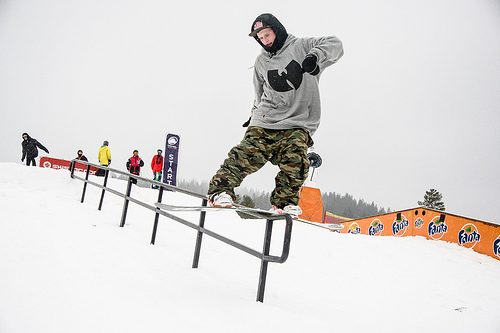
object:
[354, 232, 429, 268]
snow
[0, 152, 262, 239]
hill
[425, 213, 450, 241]
logo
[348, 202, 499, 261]
fence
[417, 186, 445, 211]
tree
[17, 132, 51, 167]
people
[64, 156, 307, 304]
rail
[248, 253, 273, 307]
pole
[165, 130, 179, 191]
sign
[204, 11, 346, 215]
boy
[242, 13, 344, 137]
hoodie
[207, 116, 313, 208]
camoflauge pants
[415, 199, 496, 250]
divider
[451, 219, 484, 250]
fanta soda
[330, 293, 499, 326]
ground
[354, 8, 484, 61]
sky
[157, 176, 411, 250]
mountain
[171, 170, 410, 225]
trees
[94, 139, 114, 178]
person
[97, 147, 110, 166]
yellow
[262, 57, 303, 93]
emblem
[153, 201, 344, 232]
snowboard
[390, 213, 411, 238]
sign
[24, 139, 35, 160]
black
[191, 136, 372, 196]
background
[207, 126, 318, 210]
fatigue pants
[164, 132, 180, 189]
starting point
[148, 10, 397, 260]
performance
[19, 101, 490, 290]
event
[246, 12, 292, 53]
hat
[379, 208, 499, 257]
advertisement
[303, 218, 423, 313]
winter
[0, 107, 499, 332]
ski resort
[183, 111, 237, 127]
distance